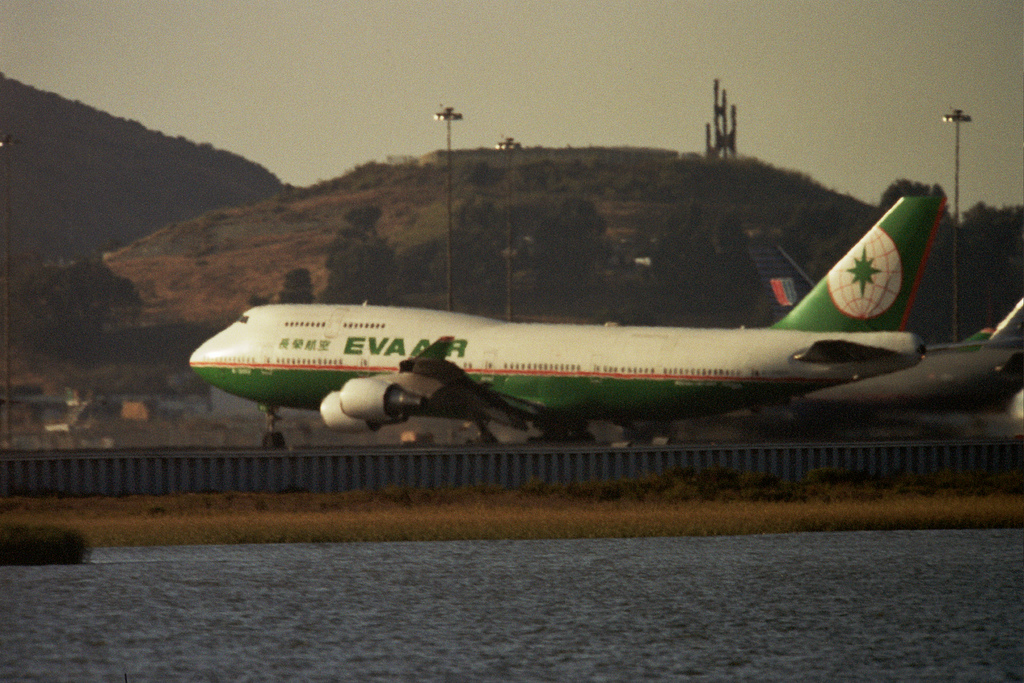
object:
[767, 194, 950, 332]
tail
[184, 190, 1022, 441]
plane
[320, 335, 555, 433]
wing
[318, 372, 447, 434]
engine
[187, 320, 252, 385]
nose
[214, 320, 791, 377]
windows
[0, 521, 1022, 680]
water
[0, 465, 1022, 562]
grass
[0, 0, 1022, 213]
sky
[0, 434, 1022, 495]
gate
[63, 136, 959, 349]
hills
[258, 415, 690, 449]
wheels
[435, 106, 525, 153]
lights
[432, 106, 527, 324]
pole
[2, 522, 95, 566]
bush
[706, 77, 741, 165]
object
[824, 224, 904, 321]
logo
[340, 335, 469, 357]
letters